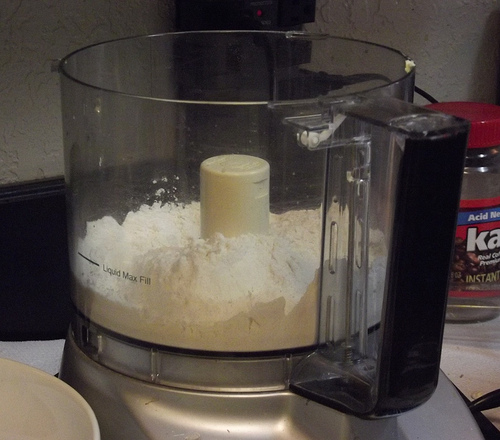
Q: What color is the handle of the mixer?
A: Black.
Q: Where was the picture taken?
A: Kitchen.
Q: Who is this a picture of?
A: Nobody.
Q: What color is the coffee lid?
A: Red.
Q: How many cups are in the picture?
A: 0.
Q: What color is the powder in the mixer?
A: White.